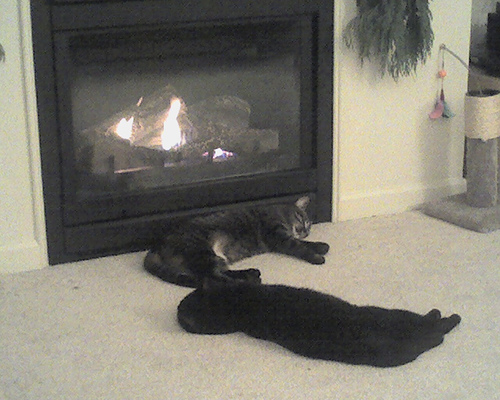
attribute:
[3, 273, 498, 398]
floor — black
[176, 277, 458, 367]
fur — black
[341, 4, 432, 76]
plant — green, hanging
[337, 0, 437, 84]
fern — green, hanging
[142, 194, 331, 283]
grey cat — gray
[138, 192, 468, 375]
cats — lying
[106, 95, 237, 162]
fire — hot, bright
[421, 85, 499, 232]
post — grey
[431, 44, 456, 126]
toy — hanging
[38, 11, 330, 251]
fireplace — black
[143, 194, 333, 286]
cat — warm, striped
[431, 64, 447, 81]
ball — yellow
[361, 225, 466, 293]
carpet — beige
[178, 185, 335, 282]
cat — grey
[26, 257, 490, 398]
carpet — beige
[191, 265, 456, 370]
cat — large, black, gray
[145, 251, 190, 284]
tail — long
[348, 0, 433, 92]
plant — hangs